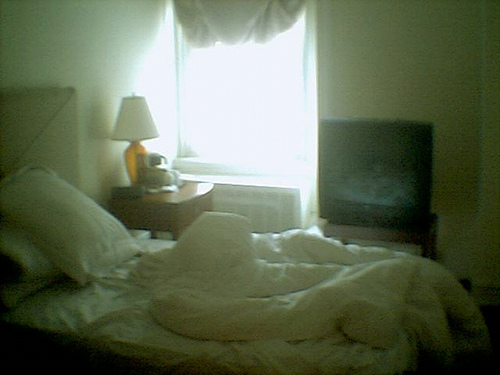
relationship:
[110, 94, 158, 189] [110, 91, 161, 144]
lamp with white shade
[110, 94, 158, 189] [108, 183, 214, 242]
lamp on a nightstand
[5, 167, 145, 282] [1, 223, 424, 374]
white pillow lying on bed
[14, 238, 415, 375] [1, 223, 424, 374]
sheets lying on bed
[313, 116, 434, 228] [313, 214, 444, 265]
tv on a stand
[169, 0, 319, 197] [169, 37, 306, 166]
window with light coming through it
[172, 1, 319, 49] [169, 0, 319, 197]
white curtain above window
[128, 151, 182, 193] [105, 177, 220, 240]
things on nightstand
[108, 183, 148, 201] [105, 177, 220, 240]
alarm clock on nightstand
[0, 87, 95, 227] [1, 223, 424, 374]
headboard above bed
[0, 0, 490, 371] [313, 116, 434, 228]
room has tv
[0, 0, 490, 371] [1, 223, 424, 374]
room has bed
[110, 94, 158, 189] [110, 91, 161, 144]
lamp has white shade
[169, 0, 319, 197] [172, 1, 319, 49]
window with white curtain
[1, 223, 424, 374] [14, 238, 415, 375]
bed with sheets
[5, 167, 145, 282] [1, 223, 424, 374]
white pillow on bed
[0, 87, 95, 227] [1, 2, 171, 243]
headboard on wall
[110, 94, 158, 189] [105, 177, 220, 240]
lamp on nightstand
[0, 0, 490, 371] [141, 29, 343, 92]
room sunlit and blurry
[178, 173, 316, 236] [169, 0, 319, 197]
airconditioner beneath window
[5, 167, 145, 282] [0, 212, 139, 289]
vertical pillow on top of horizontal pillow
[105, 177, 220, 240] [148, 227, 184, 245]
nightstand has thin legs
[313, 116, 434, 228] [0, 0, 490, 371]
tv in room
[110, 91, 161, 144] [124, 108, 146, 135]
shade of lamp white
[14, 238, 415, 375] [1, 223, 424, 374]
sheets on bed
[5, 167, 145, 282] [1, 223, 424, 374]
white pillow on top of bed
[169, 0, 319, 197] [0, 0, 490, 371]
window in room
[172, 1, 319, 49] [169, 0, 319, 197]
curtain at top of window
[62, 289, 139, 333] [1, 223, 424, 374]
wrinkles in sheets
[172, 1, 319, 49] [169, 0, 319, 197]
white curtain draped over window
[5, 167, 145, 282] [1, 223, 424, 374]
white pillow on head of bed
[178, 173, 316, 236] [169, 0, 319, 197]
airconditioner underneath window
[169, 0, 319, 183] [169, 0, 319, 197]
window with light coming